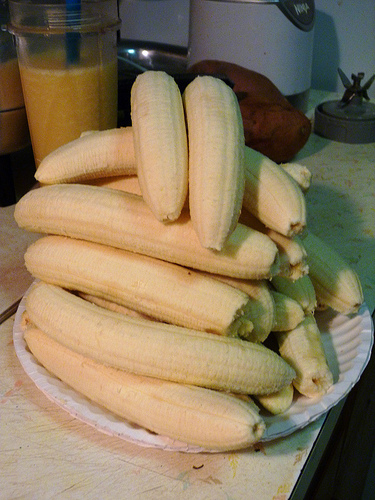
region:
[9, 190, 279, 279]
a peeled banana in a plate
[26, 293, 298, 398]
a peeled banana in a plate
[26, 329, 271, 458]
a peeled banana in a plate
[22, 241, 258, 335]
a peeled banana in a plate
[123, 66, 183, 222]
a peeled banana in a plate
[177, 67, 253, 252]
a peeled banana in a plate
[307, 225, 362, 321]
a peeled banana in a plate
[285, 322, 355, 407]
a peeled banana in a plate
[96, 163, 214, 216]
a peeled banana in a plate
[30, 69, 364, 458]
A pile of bannanas on the plate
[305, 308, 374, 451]
A pile of white paper plates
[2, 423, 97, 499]
cut marks on the white counter top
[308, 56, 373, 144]
The blades of the blender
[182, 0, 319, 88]
The base of the ninja blender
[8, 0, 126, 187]
A glass on the counter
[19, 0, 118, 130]
Orange juice in the cup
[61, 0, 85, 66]
A blue utensil in the orange juice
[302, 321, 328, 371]
A mushy patch on the banana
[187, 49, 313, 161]
Vegetables on the white counter top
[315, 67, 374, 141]
double blades for blender or food processor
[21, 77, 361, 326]
Stack of of whole peeled bananas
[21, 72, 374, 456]
Peeled whole bananas stacked on paper plates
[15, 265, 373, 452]
Three paper plates holding peeled bananas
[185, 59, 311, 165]
One raw unpeeled yam or sweet potato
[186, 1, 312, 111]
White and black trimmed Ninja food processor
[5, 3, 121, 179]
Glass food processor jar containing orange juice with pulp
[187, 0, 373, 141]
White Ninja food processor and detached blades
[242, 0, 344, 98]
Ninja food processor and it's shadow projected on wall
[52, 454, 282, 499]
Scratched cut formica counter top with floral leaf pattern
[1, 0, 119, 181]
blender container filled with orange juice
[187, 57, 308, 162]
large sweet potato laying on counter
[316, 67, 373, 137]
blender blades sitting on counter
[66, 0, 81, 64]
large blue straw inside blender container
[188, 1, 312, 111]
white blender base sitting on counter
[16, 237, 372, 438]
white paper plate sitting on counter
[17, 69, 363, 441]
stack of bananas sitting on white paper plate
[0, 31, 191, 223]
stainless steel sink sitting inside counter top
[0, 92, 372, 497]
tan counter top with scratched surface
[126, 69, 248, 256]
two bananas sitting on top of bananas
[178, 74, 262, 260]
this is a ripe banana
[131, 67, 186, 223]
this is a ripe banana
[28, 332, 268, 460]
this is a ripe banana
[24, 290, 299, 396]
this is a ripe banana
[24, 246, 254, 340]
this is a ripe banana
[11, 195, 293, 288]
this is a ripe banana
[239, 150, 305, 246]
this is a ripe banana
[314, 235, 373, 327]
this is a ripe banana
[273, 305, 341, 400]
this is a ripe banana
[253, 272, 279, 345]
this is a ripe banana